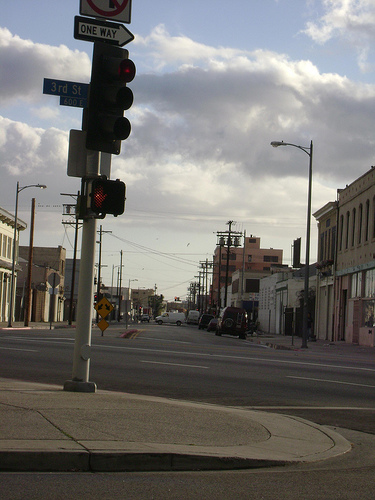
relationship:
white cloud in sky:
[296, 0, 374, 76] [0, 0, 373, 291]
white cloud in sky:
[123, 172, 312, 240] [0, 0, 373, 291]